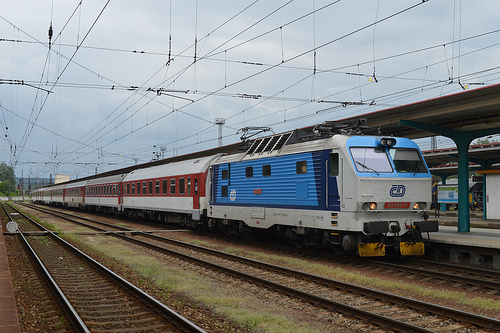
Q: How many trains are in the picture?
A: One.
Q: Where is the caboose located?
A: In the back.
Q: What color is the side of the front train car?
A: Blue.